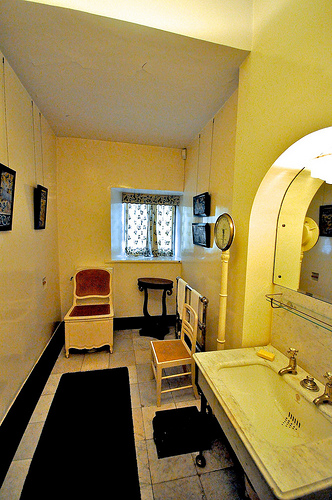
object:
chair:
[146, 304, 198, 405]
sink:
[178, 341, 331, 493]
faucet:
[276, 341, 328, 420]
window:
[107, 182, 184, 264]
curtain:
[121, 195, 176, 259]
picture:
[1, 164, 54, 232]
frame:
[0, 162, 16, 234]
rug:
[13, 365, 162, 500]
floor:
[0, 318, 232, 499]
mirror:
[267, 152, 331, 311]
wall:
[224, 78, 328, 395]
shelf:
[266, 295, 330, 341]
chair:
[64, 267, 119, 362]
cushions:
[68, 265, 109, 319]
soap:
[256, 348, 275, 362]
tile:
[138, 448, 210, 499]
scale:
[150, 400, 209, 448]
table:
[135, 274, 173, 339]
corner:
[130, 233, 186, 342]